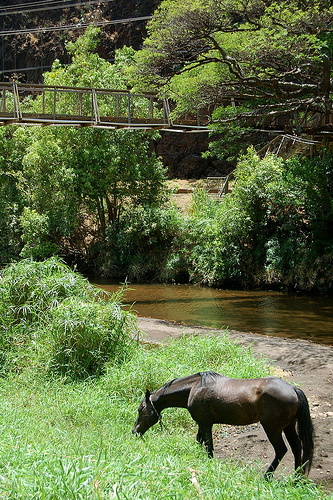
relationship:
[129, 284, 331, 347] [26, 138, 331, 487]
river lying in nature area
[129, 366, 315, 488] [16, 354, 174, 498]
horse grazes in grass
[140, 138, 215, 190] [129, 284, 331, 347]
area across from river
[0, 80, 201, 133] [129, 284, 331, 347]
bridge on river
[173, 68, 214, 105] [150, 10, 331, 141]
leaves on trees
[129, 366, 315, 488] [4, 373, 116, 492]
horse in grass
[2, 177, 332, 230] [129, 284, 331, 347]
terrain across river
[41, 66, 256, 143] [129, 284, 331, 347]
bridge above river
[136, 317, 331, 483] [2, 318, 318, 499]
ground area near grass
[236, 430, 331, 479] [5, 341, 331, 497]
rocks on ground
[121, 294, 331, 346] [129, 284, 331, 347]
reflections in river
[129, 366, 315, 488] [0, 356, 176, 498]
horse in grass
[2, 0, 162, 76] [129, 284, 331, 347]
electric wires above river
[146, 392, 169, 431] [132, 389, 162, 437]
strap on head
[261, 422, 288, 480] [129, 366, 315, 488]
leg on horse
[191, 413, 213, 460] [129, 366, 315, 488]
leg on horse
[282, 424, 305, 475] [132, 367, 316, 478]
leg on horse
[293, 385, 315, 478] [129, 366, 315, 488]
tail of horse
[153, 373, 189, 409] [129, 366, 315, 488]
neck of horse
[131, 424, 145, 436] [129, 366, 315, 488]
mouth of horse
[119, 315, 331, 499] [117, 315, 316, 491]
sand on ground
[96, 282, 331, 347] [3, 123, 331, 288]
river runs near bushes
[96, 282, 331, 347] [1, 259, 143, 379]
river runs near bushes